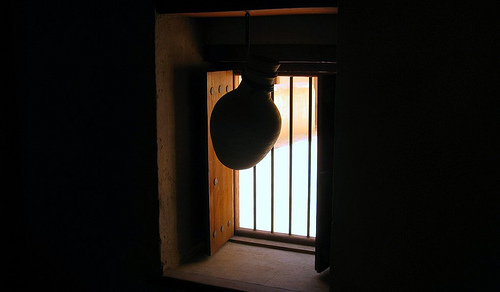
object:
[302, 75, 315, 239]
bars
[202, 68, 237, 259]
door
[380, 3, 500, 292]
wall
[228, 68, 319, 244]
window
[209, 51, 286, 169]
object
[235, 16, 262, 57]
rope